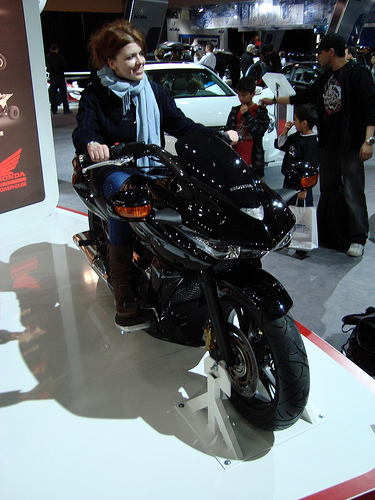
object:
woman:
[71, 21, 239, 333]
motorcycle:
[71, 128, 311, 431]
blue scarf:
[97, 68, 161, 148]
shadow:
[0, 241, 277, 462]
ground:
[26, 214, 57, 399]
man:
[258, 30, 374, 257]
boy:
[225, 76, 270, 178]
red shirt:
[234, 103, 255, 165]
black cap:
[315, 30, 353, 62]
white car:
[138, 58, 249, 130]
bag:
[226, 127, 254, 139]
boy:
[273, 102, 322, 258]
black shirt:
[274, 131, 317, 177]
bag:
[286, 199, 315, 244]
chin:
[238, 98, 250, 105]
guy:
[244, 38, 269, 76]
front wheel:
[206, 282, 311, 432]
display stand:
[178, 355, 244, 462]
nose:
[293, 120, 296, 126]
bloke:
[198, 38, 221, 74]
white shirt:
[197, 50, 224, 77]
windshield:
[154, 68, 226, 96]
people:
[176, 34, 310, 89]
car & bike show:
[123, 60, 276, 196]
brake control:
[78, 146, 140, 164]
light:
[233, 195, 266, 227]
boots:
[93, 237, 146, 334]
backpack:
[340, 295, 375, 377]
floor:
[300, 261, 374, 304]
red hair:
[89, 19, 148, 66]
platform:
[73, 400, 172, 466]